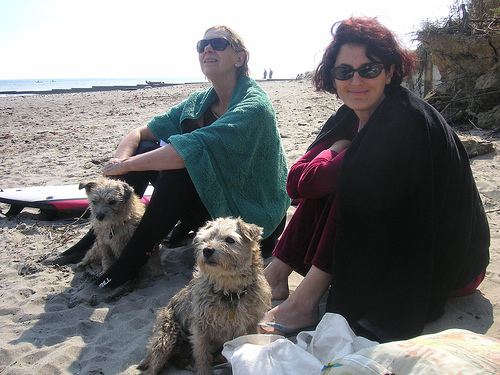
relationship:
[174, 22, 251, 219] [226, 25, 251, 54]
woman has hair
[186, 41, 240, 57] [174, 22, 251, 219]
sunglasses on woman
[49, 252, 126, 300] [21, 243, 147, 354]
feet in sand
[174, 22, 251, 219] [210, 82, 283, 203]
woman wearing shawl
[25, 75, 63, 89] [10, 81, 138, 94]
people in water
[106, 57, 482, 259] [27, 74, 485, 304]
women on beach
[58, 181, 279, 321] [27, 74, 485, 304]
dogs on beach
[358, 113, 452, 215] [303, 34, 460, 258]
towel on woman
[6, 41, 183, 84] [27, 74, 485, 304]
ocean by beach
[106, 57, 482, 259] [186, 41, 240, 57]
women wearing sunglasses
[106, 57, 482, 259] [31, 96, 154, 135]
women sitting on sand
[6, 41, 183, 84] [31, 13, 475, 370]
ocean in photo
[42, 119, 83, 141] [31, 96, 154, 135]
footprints in sand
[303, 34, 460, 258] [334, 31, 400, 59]
woman has hair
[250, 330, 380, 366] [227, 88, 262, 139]
towel on shoulders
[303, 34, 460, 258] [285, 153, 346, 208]
woman wearing shirt